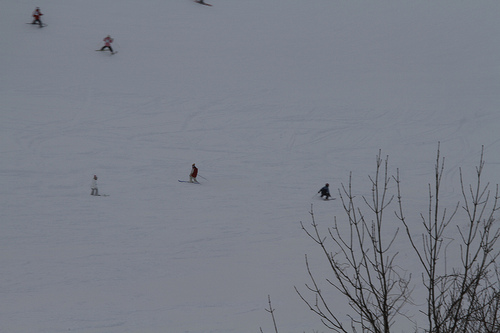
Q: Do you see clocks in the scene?
A: No, there are no clocks.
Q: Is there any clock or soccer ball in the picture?
A: No, there are no clocks or soccer balls.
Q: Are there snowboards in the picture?
A: No, there are no snowboards.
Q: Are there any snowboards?
A: No, there are no snowboards.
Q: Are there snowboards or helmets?
A: No, there are no snowboards or helmets.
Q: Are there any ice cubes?
A: No, there are no ice cubes.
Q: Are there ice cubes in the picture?
A: No, there are no ice cubes.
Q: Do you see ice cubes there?
A: No, there are no ice cubes.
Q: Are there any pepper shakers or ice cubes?
A: No, there are no ice cubes or pepper shakers.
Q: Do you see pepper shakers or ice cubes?
A: No, there are no ice cubes or pepper shakers.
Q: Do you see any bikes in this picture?
A: No, there are no bikes.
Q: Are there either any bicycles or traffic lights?
A: No, there are no bicycles or traffic lights.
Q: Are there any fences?
A: No, there are no fences.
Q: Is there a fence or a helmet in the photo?
A: No, there are no fences or helmets.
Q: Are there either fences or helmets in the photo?
A: No, there are no fences or helmets.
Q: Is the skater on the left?
A: Yes, the skater is on the left of the image.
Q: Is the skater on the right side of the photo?
A: No, the skater is on the left of the image.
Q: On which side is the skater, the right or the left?
A: The skater is on the left of the image.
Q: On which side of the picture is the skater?
A: The skater is on the left of the image.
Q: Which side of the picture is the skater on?
A: The skater is on the left of the image.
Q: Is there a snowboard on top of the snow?
A: No, there is a skater on top of the snow.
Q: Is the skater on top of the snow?
A: Yes, the skater is on top of the snow.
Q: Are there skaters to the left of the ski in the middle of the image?
A: Yes, there is a skater to the left of the ski.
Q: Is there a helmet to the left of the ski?
A: No, there is a skater to the left of the ski.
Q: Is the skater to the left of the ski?
A: Yes, the skater is to the left of the ski.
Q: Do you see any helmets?
A: No, there are no helmets.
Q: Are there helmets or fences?
A: No, there are no helmets or fences.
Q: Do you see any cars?
A: No, there are no cars.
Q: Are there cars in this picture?
A: No, there are no cars.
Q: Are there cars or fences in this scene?
A: No, there are no cars or fences.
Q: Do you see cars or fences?
A: No, there are no cars or fences.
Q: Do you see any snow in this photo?
A: Yes, there is snow.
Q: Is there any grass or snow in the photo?
A: Yes, there is snow.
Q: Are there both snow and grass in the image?
A: No, there is snow but no grass.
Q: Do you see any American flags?
A: No, there are no American flags.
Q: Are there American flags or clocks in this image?
A: No, there are no American flags or clocks.